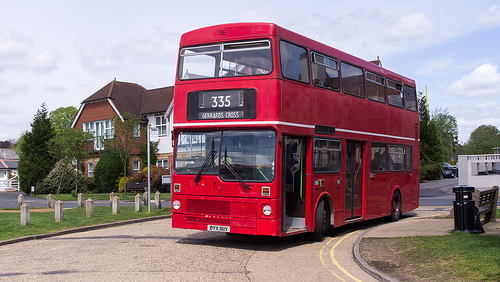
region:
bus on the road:
[158, 21, 430, 246]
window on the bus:
[275, 49, 310, 87]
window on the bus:
[311, 55, 340, 89]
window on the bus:
[343, 68, 360, 95]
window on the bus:
[363, 70, 383, 98]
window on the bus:
[388, 85, 401, 104]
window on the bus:
[405, 85, 417, 112]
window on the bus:
[313, 136, 335, 171]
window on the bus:
[364, 143, 388, 173]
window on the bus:
[388, 146, 403, 164]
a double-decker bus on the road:
[158, 19, 433, 246]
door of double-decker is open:
[275, 122, 315, 242]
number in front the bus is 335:
[181, 81, 252, 119]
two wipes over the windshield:
[167, 131, 262, 195]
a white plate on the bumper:
[194, 215, 239, 237]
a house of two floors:
[60, 70, 171, 195]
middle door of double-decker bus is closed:
[340, 125, 370, 220]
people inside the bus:
[282, 132, 404, 170]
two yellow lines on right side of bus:
[301, 232, 351, 277]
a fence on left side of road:
[14, 181, 168, 221]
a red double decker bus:
[169, 20, 422, 239]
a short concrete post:
[51, 198, 66, 221]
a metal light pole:
[145, 118, 159, 213]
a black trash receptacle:
[450, 181, 479, 236]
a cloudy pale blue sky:
[0, 1, 497, 143]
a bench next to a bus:
[470, 182, 499, 224]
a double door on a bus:
[346, 138, 366, 221]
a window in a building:
[85, 159, 96, 177]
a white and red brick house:
[68, 77, 170, 188]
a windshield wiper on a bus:
[190, 135, 216, 186]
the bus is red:
[168, 23, 423, 234]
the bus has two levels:
[164, 25, 421, 236]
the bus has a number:
[176, 23, 423, 239]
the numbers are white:
[206, 93, 237, 108]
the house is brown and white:
[71, 72, 179, 188]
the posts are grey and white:
[13, 193, 170, 225]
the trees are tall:
[21, 105, 72, 185]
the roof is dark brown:
[76, 79, 172, 114]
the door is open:
[277, 133, 313, 230]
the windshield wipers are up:
[193, 145, 253, 197]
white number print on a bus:
[208, 95, 234, 107]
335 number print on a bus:
[208, 95, 231, 107]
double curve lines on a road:
[318, 231, 368, 280]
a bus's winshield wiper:
[191, 147, 218, 183]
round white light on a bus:
[260, 203, 271, 215]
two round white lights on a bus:
[170, 198, 272, 215]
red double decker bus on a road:
[169, 21, 423, 241]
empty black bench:
[476, 183, 498, 222]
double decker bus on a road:
[168, 21, 423, 241]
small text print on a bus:
[199, 110, 241, 118]